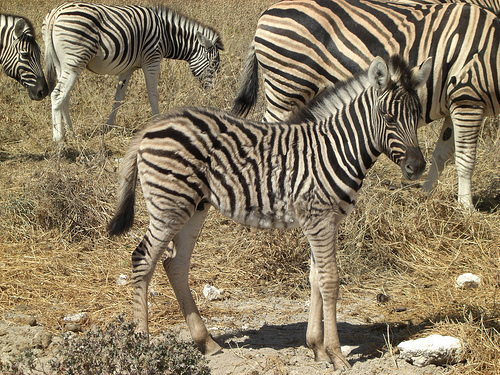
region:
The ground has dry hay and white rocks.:
[1, 0, 498, 372]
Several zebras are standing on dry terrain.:
[1, 0, 498, 373]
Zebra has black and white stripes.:
[101, 52, 434, 374]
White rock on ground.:
[392, 331, 467, 368]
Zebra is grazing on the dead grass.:
[37, 4, 227, 147]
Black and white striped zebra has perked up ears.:
[102, 52, 435, 374]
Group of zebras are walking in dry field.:
[0, 0, 499, 372]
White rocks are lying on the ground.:
[0, 269, 499, 369]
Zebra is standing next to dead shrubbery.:
[0, 53, 435, 374]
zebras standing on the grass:
[1, 0, 497, 372]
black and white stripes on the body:
[96, 46, 426, 361]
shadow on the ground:
[195, 320, 420, 360]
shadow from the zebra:
[195, 306, 427, 368]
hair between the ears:
[385, 50, 410, 95]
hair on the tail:
[95, 126, 141, 236]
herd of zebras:
[1, 0, 492, 374]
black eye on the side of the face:
[18, 48, 31, 63]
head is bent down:
[180, 17, 237, 105]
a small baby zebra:
[90, 76, 434, 336]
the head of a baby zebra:
[352, 52, 463, 179]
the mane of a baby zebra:
[272, 75, 377, 112]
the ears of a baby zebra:
[355, 36, 437, 94]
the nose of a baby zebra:
[388, 139, 429, 171]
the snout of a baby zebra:
[387, 156, 431, 176]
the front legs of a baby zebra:
[288, 219, 349, 347]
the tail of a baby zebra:
[95, 169, 172, 253]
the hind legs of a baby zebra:
[118, 218, 215, 333]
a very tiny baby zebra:
[93, 82, 448, 352]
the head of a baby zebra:
[350, 55, 438, 180]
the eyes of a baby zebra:
[376, 104, 430, 131]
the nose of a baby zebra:
[406, 145, 427, 175]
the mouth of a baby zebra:
[395, 162, 421, 183]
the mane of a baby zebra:
[373, 45, 418, 85]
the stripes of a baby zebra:
[295, 118, 355, 196]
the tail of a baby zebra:
[73, 164, 177, 230]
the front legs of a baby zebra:
[280, 227, 380, 361]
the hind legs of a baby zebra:
[87, 210, 244, 352]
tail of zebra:
[110, 153, 133, 236]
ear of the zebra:
[366, 55, 428, 90]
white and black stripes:
[320, 130, 350, 195]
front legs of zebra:
[305, 220, 340, 370]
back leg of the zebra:
[131, 240, 156, 325]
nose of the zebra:
[405, 157, 425, 169]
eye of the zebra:
[380, 110, 395, 122]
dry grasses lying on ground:
[362, 202, 443, 272]